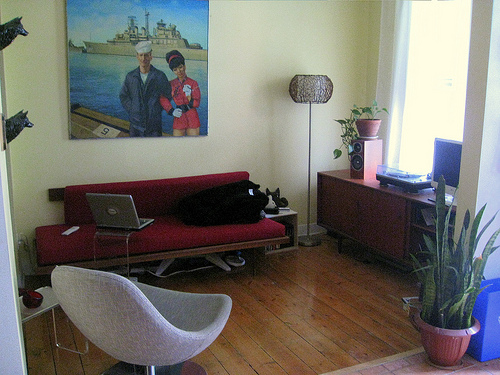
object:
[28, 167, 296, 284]
couch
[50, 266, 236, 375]
chair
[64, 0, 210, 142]
painting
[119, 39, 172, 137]
sailor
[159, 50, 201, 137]
woman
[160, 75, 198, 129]
red outfit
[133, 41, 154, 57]
hat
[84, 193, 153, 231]
laptop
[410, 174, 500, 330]
plant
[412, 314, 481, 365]
brown container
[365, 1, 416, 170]
curtains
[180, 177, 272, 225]
black object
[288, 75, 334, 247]
lamp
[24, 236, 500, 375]
floors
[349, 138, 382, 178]
speaker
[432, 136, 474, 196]
television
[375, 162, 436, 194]
record player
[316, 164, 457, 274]
cabinet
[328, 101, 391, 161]
plant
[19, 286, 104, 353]
table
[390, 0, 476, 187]
window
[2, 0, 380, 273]
wall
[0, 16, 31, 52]
statie